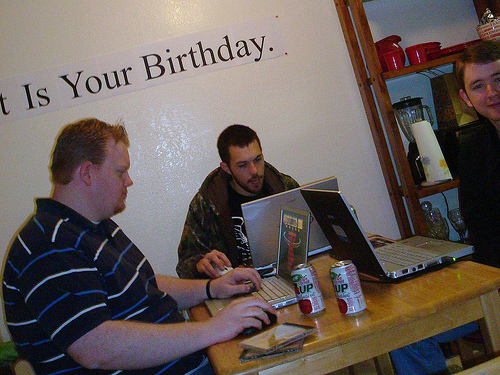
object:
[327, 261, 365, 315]
cans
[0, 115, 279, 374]
man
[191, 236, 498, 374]
table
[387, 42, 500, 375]
man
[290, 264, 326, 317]
soda can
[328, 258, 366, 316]
soda can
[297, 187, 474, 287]
laptop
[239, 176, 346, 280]
laptop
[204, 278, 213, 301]
bracelet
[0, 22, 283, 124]
sign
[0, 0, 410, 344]
wall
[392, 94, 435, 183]
blender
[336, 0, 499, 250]
shelf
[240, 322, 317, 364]
disks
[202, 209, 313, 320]
laptops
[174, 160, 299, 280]
jacket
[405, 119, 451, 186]
towel paper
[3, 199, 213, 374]
shirt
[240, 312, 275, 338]
mouse